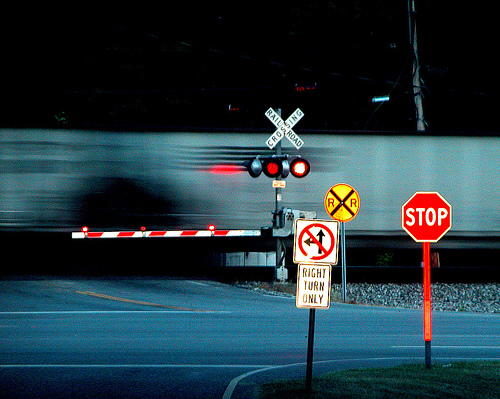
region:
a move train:
[30, 71, 485, 306]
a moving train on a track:
[16, 73, 476, 313]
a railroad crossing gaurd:
[65, 102, 372, 312]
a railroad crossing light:
[57, 92, 312, 291]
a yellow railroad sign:
[319, 182, 369, 291]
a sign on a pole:
[305, 172, 375, 316]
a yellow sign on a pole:
[311, 180, 372, 305]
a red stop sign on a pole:
[393, 181, 470, 368]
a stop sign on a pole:
[379, 180, 481, 382]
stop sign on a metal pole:
[389, 170, 474, 380]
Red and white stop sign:
[397, 162, 456, 349]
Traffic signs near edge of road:
[239, 173, 459, 353]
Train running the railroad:
[51, 133, 285, 283]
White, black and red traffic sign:
[293, 212, 340, 347]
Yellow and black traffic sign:
[316, 171, 370, 221]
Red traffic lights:
[245, 152, 317, 183]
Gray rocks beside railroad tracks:
[443, 280, 498, 312]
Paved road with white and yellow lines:
[14, 288, 206, 390]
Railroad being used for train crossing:
[23, 140, 298, 297]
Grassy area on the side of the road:
[373, 365, 485, 396]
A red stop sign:
[396, 183, 466, 371]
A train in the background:
[5, 121, 498, 258]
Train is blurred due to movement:
[3, 117, 496, 267]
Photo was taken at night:
[3, 8, 499, 317]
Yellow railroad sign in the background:
[322, 181, 367, 299]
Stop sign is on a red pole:
[395, 186, 460, 368]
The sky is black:
[2, 1, 499, 126]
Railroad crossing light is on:
[242, 154, 315, 188]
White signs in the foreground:
[283, 216, 343, 391]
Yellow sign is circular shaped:
[321, 177, 369, 232]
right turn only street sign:
[286, 207, 357, 364]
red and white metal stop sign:
[394, 172, 459, 347]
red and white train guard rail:
[68, 182, 317, 272]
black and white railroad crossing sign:
[237, 94, 321, 156]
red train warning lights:
[242, 146, 323, 222]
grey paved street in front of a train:
[10, 266, 498, 381]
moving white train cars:
[18, 121, 486, 248]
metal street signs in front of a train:
[258, 93, 460, 313]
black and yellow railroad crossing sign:
[321, 171, 371, 233]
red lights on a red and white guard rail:
[73, 219, 278, 255]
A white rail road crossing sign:
[263, 106, 305, 150]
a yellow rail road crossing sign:
[324, 183, 359, 222]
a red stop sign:
[399, 190, 451, 241]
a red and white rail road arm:
[73, 208, 313, 240]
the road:
[2, 277, 498, 397]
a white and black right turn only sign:
[297, 263, 331, 308]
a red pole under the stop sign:
[422, 244, 433, 366]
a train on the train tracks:
[0, 126, 498, 281]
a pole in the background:
[407, 0, 427, 131]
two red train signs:
[245, 154, 310, 179]